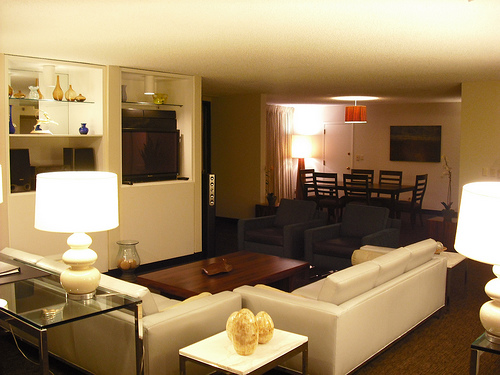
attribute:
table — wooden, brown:
[137, 249, 307, 296]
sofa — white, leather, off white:
[230, 237, 448, 374]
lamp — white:
[34, 169, 121, 301]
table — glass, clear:
[3, 253, 146, 374]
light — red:
[343, 99, 367, 124]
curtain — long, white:
[265, 104, 294, 203]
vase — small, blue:
[78, 123, 89, 135]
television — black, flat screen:
[121, 127, 182, 183]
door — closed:
[321, 120, 354, 184]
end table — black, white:
[179, 321, 310, 374]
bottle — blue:
[8, 103, 16, 134]